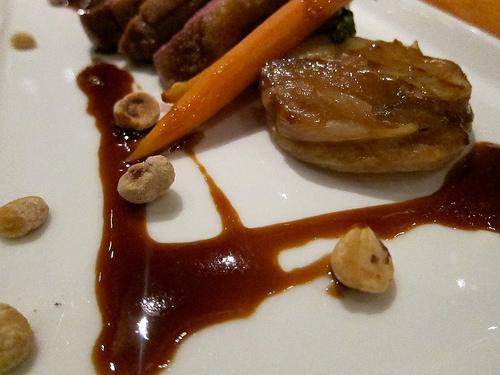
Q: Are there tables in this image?
A: Yes, there is a table.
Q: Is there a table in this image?
A: Yes, there is a table.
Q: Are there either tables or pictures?
A: Yes, there is a table.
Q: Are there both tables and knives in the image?
A: No, there is a table but no knives.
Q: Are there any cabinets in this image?
A: No, there are no cabinets.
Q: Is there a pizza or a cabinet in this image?
A: No, there are no cabinets or pizzas.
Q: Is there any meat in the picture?
A: Yes, there is meat.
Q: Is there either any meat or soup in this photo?
A: Yes, there is meat.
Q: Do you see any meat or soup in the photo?
A: Yes, there is meat.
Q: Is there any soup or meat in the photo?
A: Yes, there is meat.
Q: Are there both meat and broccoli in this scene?
A: No, there is meat but no broccoli.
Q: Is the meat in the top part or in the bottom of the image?
A: The meat is in the top of the image.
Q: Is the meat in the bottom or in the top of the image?
A: The meat is in the top of the image.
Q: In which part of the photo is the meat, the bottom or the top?
A: The meat is in the top of the image.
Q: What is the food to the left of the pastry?
A: The food is meat.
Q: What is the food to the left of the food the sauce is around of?
A: The food is meat.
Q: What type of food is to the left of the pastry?
A: The food is meat.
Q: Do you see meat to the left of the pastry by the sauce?
A: Yes, there is meat to the left of the pastry.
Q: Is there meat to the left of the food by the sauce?
A: Yes, there is meat to the left of the pastry.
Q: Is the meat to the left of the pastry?
A: Yes, the meat is to the left of the pastry.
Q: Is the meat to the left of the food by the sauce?
A: Yes, the meat is to the left of the pastry.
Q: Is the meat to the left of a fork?
A: No, the meat is to the left of the pastry.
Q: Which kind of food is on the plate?
A: The food is meat.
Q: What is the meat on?
A: The meat is on the plate.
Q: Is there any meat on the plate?
A: Yes, there is meat on the plate.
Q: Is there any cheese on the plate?
A: No, there is meat on the plate.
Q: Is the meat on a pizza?
A: No, the meat is on the plate.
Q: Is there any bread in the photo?
A: No, there is no breads.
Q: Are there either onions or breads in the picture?
A: No, there are no breads or onions.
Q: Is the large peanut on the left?
A: Yes, the peanut is on the left of the image.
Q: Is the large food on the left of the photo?
A: Yes, the peanut is on the left of the image.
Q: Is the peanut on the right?
A: No, the peanut is on the left of the image.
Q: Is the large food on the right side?
A: No, the peanut is on the left of the image.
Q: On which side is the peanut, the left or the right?
A: The peanut is on the left of the image.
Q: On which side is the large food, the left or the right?
A: The peanut is on the left of the image.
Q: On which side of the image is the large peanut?
A: The peanut is on the left of the image.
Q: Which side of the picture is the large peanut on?
A: The peanut is on the left of the image.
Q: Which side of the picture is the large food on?
A: The peanut is on the left of the image.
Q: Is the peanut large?
A: Yes, the peanut is large.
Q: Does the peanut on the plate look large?
A: Yes, the peanut is large.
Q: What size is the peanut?
A: The peanut is large.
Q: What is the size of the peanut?
A: The peanut is large.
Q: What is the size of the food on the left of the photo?
A: The peanut is large.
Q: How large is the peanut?
A: The peanut is large.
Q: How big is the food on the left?
A: The peanut is large.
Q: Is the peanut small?
A: No, the peanut is large.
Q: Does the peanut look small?
A: No, the peanut is large.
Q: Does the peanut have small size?
A: No, the peanut is large.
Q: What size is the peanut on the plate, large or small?
A: The peanut is large.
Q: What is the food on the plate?
A: The food is a peanut.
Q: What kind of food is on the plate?
A: The food is a peanut.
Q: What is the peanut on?
A: The peanut is on the plate.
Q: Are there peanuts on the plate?
A: Yes, there is a peanut on the plate.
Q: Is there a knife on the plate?
A: No, there is a peanut on the plate.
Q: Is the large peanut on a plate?
A: Yes, the peanut is on a plate.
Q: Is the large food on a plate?
A: Yes, the peanut is on a plate.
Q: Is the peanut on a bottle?
A: No, the peanut is on a plate.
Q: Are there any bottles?
A: No, there are no bottles.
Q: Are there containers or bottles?
A: No, there are no bottles or containers.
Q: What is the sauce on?
A: The sauce is on the plate.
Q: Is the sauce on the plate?
A: Yes, the sauce is on the plate.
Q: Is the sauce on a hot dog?
A: No, the sauce is on the plate.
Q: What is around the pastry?
A: The sauce is around the pastry.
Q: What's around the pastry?
A: The sauce is around the pastry.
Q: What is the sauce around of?
A: The sauce is around the pastry.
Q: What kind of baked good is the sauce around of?
A: The sauce is around the pastry.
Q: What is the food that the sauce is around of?
A: The food is a pastry.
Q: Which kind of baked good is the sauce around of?
A: The sauce is around the pastry.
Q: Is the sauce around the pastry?
A: Yes, the sauce is around the pastry.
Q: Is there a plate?
A: Yes, there is a plate.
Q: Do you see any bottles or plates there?
A: Yes, there is a plate.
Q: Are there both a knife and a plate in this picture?
A: No, there is a plate but no knives.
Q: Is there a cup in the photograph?
A: No, there are no cups.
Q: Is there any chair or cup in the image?
A: No, there are no cups or chairs.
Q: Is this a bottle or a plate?
A: This is a plate.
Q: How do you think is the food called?
A: The food is a pastry.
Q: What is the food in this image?
A: The food is a pastry.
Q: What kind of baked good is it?
A: The food is a pastry.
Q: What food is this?
A: This is a pastry.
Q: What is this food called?
A: This is a pastry.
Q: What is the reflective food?
A: The food is a pastry.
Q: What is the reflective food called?
A: The food is a pastry.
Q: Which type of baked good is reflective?
A: The baked good is a pastry.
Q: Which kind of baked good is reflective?
A: The baked good is a pastry.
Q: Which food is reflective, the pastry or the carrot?
A: The pastry is reflective.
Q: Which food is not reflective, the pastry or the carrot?
A: The carrot is not reflective.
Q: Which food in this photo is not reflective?
A: The food is a carrot.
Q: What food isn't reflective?
A: The food is a carrot.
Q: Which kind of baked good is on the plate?
A: The food is a pastry.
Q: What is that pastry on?
A: The pastry is on the plate.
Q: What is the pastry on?
A: The pastry is on the plate.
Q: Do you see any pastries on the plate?
A: Yes, there is a pastry on the plate.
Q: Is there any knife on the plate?
A: No, there is a pastry on the plate.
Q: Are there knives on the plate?
A: No, there is a pastry on the plate.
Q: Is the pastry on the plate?
A: Yes, the pastry is on the plate.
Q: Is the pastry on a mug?
A: No, the pastry is on the plate.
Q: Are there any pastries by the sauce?
A: Yes, there is a pastry by the sauce.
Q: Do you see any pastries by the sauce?
A: Yes, there is a pastry by the sauce.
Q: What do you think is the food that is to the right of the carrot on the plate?
A: The food is a pastry.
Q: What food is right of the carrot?
A: The food is a pastry.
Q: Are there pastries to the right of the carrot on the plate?
A: Yes, there is a pastry to the right of the carrot.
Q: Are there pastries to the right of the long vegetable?
A: Yes, there is a pastry to the right of the carrot.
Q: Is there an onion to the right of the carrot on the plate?
A: No, there is a pastry to the right of the carrot.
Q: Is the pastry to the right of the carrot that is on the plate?
A: Yes, the pastry is to the right of the carrot.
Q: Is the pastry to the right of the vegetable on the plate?
A: Yes, the pastry is to the right of the carrot.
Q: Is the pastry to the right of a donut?
A: No, the pastry is to the right of the carrot.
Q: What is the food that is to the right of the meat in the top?
A: The food is a pastry.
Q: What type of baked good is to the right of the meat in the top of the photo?
A: The food is a pastry.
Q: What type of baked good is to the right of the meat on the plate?
A: The food is a pastry.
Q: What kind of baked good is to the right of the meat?
A: The food is a pastry.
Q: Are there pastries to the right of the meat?
A: Yes, there is a pastry to the right of the meat.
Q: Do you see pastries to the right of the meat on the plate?
A: Yes, there is a pastry to the right of the meat.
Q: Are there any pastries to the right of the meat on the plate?
A: Yes, there is a pastry to the right of the meat.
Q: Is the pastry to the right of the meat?
A: Yes, the pastry is to the right of the meat.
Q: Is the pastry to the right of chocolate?
A: No, the pastry is to the right of the meat.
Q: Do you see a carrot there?
A: Yes, there is a carrot.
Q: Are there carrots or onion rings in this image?
A: Yes, there is a carrot.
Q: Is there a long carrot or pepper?
A: Yes, there is a long carrot.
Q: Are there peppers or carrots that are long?
A: Yes, the carrot is long.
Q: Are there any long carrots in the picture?
A: Yes, there is a long carrot.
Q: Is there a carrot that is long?
A: Yes, there is a carrot that is long.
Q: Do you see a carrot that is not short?
A: Yes, there is a long carrot.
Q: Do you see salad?
A: No, there is no salad.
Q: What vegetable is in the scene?
A: The vegetable is a carrot.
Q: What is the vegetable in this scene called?
A: The vegetable is a carrot.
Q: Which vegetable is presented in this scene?
A: The vegetable is a carrot.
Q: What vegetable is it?
A: The vegetable is a carrot.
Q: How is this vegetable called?
A: That is a carrot.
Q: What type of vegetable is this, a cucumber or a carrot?
A: That is a carrot.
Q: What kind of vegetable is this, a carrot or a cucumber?
A: That is a carrot.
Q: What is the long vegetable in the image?
A: The vegetable is a carrot.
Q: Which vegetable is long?
A: The vegetable is a carrot.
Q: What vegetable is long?
A: The vegetable is a carrot.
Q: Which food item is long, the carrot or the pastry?
A: The carrot is long.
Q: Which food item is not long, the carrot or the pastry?
A: The pastry is not long.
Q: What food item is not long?
A: The food item is a pastry.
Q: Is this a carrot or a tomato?
A: This is a carrot.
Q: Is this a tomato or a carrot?
A: This is a carrot.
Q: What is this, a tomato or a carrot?
A: This is a carrot.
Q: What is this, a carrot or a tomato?
A: This is a carrot.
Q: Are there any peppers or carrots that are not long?
A: No, there is a carrot but it is long.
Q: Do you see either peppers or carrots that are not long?
A: No, there is a carrot but it is long.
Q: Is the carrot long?
A: Yes, the carrot is long.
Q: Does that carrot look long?
A: Yes, the carrot is long.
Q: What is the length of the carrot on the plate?
A: The carrot is long.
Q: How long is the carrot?
A: The carrot is long.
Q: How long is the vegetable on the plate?
A: The carrot is long.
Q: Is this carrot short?
A: No, the carrot is long.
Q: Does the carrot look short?
A: No, the carrot is long.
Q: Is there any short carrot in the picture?
A: No, there is a carrot but it is long.